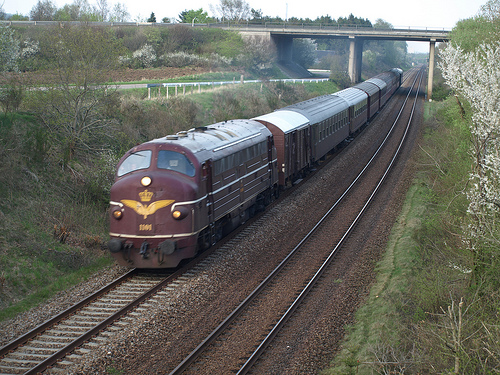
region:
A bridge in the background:
[8, 10, 470, 117]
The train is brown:
[74, 92, 498, 250]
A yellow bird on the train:
[108, 177, 189, 219]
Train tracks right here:
[193, 83, 405, 364]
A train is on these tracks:
[91, 145, 323, 336]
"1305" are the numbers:
[123, 213, 174, 245]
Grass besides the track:
[397, 93, 488, 353]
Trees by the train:
[10, 11, 350, 262]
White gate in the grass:
[47, 27, 408, 127]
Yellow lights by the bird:
[168, 202, 203, 234]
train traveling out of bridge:
[1, 1, 498, 374]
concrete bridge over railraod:
[188, 21, 453, 101]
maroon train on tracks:
[0, 63, 425, 374]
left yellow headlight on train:
[111, 208, 122, 217]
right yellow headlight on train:
[170, 208, 182, 222]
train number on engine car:
[136, 221, 153, 231]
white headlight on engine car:
[141, 176, 150, 186]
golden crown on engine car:
[137, 189, 154, 201]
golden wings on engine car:
[118, 196, 175, 218]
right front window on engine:
[155, 145, 195, 179]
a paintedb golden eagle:
[119, 194, 174, 235]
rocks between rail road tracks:
[95, 270, 220, 371]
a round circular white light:
[128, 167, 162, 199]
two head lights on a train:
[95, 205, 185, 239]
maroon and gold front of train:
[74, 155, 202, 298]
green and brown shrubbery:
[351, 166, 491, 373]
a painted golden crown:
[128, 185, 153, 203]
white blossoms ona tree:
[440, 144, 495, 259]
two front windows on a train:
[74, 139, 201, 211]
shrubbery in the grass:
[32, 218, 79, 269]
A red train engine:
[98, 120, 283, 264]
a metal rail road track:
[332, 132, 378, 244]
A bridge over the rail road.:
[338, 15, 418, 46]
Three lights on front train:
[118, 172, 178, 228]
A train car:
[306, 102, 333, 127]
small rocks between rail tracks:
[303, 210, 345, 256]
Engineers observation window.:
[148, 151, 197, 174]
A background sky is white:
[278, 3, 415, 13]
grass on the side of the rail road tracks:
[389, 217, 427, 322]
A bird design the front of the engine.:
[123, 202, 170, 218]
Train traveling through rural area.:
[34, 18, 448, 329]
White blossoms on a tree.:
[426, 30, 498, 299]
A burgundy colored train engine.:
[68, 75, 286, 282]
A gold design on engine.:
[115, 182, 180, 225]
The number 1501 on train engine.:
[128, 218, 167, 235]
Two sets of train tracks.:
[20, 265, 296, 373]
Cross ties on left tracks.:
[0, 270, 146, 370]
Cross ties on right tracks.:
[205, 227, 335, 357]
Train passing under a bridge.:
[92, 0, 434, 278]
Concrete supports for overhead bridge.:
[340, 28, 450, 95]